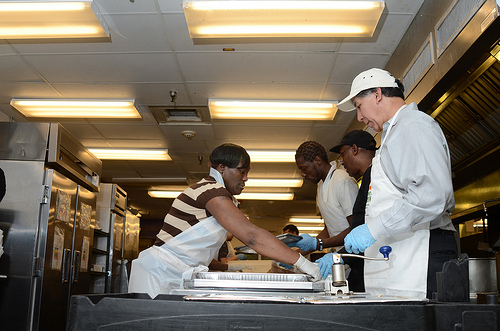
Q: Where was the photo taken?
A: In a room.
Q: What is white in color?
A: The cap.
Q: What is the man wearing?
A: A cap.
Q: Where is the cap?
A: On the man's head.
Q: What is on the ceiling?
A: Lights.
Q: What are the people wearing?
A: Aprons.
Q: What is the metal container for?
A: Food.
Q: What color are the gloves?
A: Blue.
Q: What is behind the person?
A: A fridge.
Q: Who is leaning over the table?
A: A person.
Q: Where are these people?
A: Commercial kitchen.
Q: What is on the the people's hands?
A: Gloves.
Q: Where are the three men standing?
A: They are standing on the right side of the table.